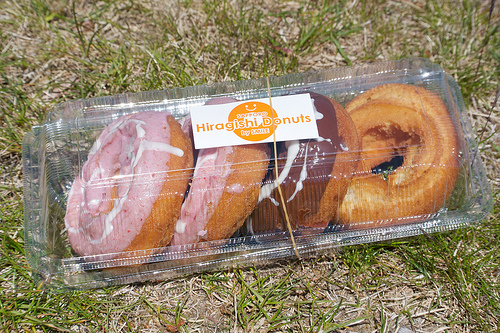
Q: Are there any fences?
A: No, there are no fences.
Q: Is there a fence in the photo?
A: No, there are no fences.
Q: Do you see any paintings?
A: No, there are no paintings.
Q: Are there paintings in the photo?
A: No, there are no paintings.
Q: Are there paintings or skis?
A: No, there are no paintings or skis.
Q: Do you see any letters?
A: Yes, there are letters.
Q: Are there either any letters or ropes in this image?
A: Yes, there are letters.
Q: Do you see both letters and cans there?
A: No, there are letters but no cans.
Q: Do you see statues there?
A: No, there are no statues.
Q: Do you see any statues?
A: No, there are no statues.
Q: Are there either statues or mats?
A: No, there are no statues or mats.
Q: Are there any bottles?
A: No, there are no bottles.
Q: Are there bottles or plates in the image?
A: No, there are no bottles or plates.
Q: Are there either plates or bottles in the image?
A: No, there are no bottles or plates.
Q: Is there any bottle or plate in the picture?
A: No, there are no bottles or plates.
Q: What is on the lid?
A: The label is on the lid.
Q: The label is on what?
A: The label is on the lid.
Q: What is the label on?
A: The label is on the lid.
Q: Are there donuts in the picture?
A: Yes, there are donuts.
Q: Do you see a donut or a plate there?
A: Yes, there are donuts.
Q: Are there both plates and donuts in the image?
A: No, there are donuts but no plates.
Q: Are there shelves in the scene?
A: No, there are no shelves.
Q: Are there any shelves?
A: No, there are no shelves.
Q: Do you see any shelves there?
A: No, there are no shelves.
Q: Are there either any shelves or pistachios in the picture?
A: No, there are no shelves or pistachios.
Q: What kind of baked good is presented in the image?
A: The baked good is donuts.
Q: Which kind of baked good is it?
A: The food is donuts.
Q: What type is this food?
A: These are donuts.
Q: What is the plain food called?
A: The food is donuts.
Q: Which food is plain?
A: The food is donuts.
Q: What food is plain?
A: The food is donuts.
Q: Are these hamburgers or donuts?
A: These are donuts.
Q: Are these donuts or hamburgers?
A: These are donuts.